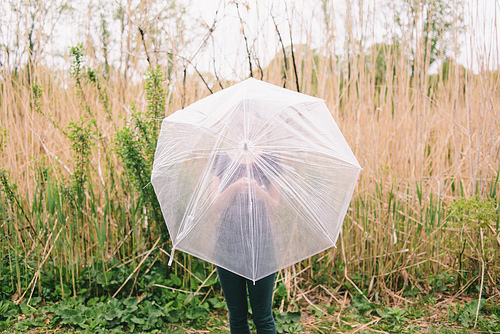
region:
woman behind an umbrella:
[119, 59, 372, 323]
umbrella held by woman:
[132, 76, 350, 265]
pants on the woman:
[212, 229, 291, 332]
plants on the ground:
[21, 265, 205, 332]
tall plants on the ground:
[59, 71, 166, 259]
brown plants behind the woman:
[11, 33, 483, 235]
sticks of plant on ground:
[319, 266, 466, 323]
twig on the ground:
[448, 227, 481, 289]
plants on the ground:
[338, 279, 413, 331]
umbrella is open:
[145, 73, 365, 285]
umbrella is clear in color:
[145, 57, 372, 288]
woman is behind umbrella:
[198, 102, 292, 332]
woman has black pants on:
[204, 104, 291, 332]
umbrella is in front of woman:
[145, 76, 352, 281]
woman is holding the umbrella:
[202, 93, 288, 330]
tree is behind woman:
[373, 0, 482, 93]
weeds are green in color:
[2, 273, 226, 330]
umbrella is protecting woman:
[148, 75, 365, 280]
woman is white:
[205, 105, 282, 332]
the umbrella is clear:
[151, 76, 358, 281]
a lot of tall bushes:
[1, 25, 498, 332]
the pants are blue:
[216, 233, 278, 333]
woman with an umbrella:
[149, 78, 362, 333]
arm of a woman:
[212, 175, 243, 212]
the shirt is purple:
[211, 152, 282, 251]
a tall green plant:
[112, 129, 172, 255]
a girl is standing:
[210, 104, 280, 332]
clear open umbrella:
[131, 60, 364, 290]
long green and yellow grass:
[390, 190, 450, 271]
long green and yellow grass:
[377, 275, 417, 311]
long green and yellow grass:
[415, 275, 465, 305]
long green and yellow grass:
[1, 217, 76, 263]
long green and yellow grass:
[97, 242, 124, 265]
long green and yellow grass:
[38, 112, 79, 142]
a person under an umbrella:
[61, 34, 441, 298]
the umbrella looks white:
[138, 72, 368, 287]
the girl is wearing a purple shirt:
[203, 142, 291, 327]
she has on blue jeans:
[206, 227, 284, 329]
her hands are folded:
[210, 172, 290, 214]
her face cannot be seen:
[216, 107, 282, 174]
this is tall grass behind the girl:
[10, 10, 161, 267]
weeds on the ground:
[15, 292, 212, 330]